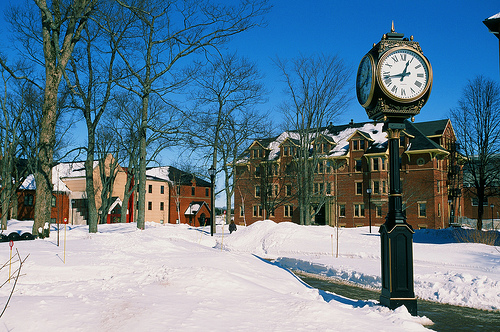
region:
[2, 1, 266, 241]
trees without leaves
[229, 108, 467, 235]
building with brick walls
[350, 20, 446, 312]
clock with roman numerals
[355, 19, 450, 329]
green clock with white face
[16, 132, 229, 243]
red and yellow buildings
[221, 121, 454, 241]
building with snow on the roof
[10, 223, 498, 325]
snow-covered ground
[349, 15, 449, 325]
tall dark green clock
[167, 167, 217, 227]
red brick building with black roof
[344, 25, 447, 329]
green and gold clock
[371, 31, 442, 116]
front face of clock with roman numeral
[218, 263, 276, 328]
clean white snow on ground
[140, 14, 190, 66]
brown tree with no leaves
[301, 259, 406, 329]
cleared path in middle of snow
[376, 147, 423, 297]
dark black pole under clock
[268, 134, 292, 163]
white snow on roof of building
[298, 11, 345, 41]
clear blue patch of sky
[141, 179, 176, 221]
windows on side of the building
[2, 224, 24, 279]
orange stakes stuck in snow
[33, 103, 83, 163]
dark brown tree trunk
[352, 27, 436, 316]
BEAUTIFUL DESIGNED CLOCK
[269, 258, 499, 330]
WALKWAY HAS BEEN SHOLVED FREE OF SNOW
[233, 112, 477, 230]
HISTORICAL LOOKING BUILDING WITH SNOW CAPS ON THE ROOF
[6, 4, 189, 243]
NATURES WONDERFUL ART OF TREES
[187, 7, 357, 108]
CLOUD FREE SKIES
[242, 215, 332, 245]
SNOW DRIFTS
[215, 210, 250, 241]
WALKING AMONG THE SNOW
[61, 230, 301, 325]
PURE WHITE SNOW IS BEAUTIFUL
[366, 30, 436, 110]
TIME IS 12:44